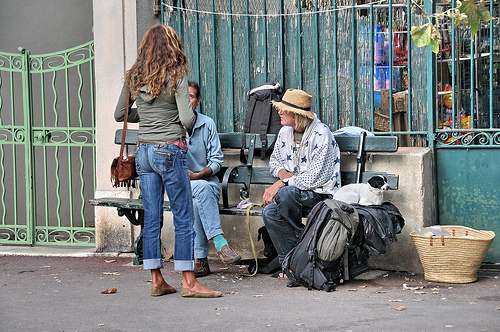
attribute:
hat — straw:
[268, 85, 321, 121]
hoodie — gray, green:
[114, 65, 198, 145]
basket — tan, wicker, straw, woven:
[409, 223, 497, 284]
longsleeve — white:
[267, 120, 343, 195]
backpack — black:
[244, 83, 281, 158]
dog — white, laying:
[331, 173, 392, 208]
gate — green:
[1, 24, 100, 247]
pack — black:
[278, 197, 346, 294]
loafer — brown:
[218, 245, 244, 268]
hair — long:
[123, 23, 189, 97]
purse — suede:
[108, 68, 136, 188]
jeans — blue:
[131, 139, 197, 272]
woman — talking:
[112, 24, 224, 298]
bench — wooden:
[86, 127, 400, 284]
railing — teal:
[159, 0, 497, 148]